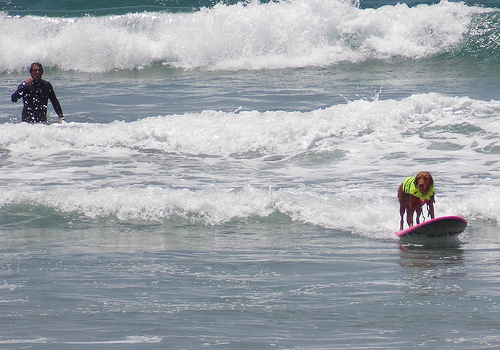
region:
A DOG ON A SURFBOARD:
[387, 165, 468, 249]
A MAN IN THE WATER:
[4, 55, 80, 137]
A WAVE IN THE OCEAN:
[162, 110, 292, 182]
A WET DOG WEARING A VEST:
[378, 165, 452, 227]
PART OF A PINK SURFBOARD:
[390, 215, 480, 250]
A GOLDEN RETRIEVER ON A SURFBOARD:
[383, 153, 432, 248]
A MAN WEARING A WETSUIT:
[10, 58, 76, 135]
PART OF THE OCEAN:
[137, 243, 284, 318]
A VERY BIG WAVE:
[158, 5, 405, 72]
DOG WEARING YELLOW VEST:
[386, 165, 450, 234]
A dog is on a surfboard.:
[393, 169, 437, 231]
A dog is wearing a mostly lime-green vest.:
[399, 167, 439, 209]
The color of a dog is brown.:
[393, 167, 438, 231]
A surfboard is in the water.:
[393, 214, 470, 245]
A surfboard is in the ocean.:
[395, 210, 469, 248]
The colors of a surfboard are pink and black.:
[392, 214, 469, 244]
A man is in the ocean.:
[10, 59, 70, 134]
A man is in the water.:
[7, 59, 71, 127]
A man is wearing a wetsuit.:
[7, 62, 67, 130]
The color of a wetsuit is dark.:
[11, 59, 67, 128]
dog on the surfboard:
[386, 167, 446, 237]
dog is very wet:
[391, 162, 446, 238]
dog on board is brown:
[388, 160, 444, 241]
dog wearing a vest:
[398, 169, 434, 210]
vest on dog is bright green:
[397, 164, 440, 212]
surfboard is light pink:
[391, 205, 471, 252]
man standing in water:
[9, 54, 76, 144]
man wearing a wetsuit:
[9, 74, 66, 131]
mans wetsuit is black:
[6, 73, 66, 131]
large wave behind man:
[4, 3, 496, 86]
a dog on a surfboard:
[386, 169, 469, 241]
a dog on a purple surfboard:
[391, 169, 468, 244]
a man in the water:
[7, 61, 66, 126]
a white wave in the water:
[0, 86, 495, 173]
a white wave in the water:
[0, 0, 495, 76]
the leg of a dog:
[395, 205, 407, 232]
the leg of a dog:
[406, 203, 416, 230]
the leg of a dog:
[423, 199, 438, 222]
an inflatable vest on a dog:
[400, 173, 436, 203]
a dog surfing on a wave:
[385, 169, 471, 241]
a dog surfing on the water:
[387, 170, 467, 245]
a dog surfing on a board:
[389, 169, 471, 245]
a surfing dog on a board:
[389, 172, 471, 243]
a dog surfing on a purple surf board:
[391, 170, 466, 247]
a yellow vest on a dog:
[400, 175, 442, 204]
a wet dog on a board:
[391, 163, 465, 245]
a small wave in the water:
[2, 95, 495, 171]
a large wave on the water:
[0, 1, 498, 88]